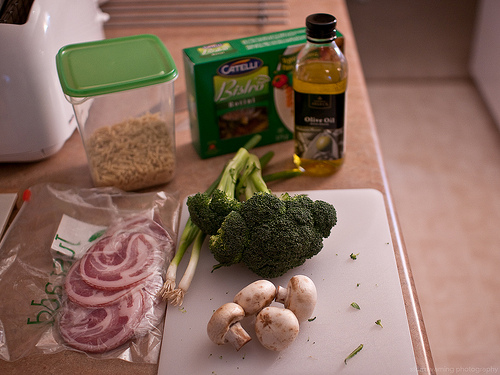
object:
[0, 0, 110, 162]
toaster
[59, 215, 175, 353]
raw meat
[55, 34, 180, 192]
container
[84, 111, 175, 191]
pasta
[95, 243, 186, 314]
onion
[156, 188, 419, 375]
board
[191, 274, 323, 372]
mushrooms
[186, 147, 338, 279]
food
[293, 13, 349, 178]
bottle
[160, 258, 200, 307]
root ends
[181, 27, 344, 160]
box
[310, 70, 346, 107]
ground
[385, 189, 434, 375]
board edge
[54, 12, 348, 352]
food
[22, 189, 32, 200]
slider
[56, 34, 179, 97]
lid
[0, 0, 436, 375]
counter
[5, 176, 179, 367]
packet